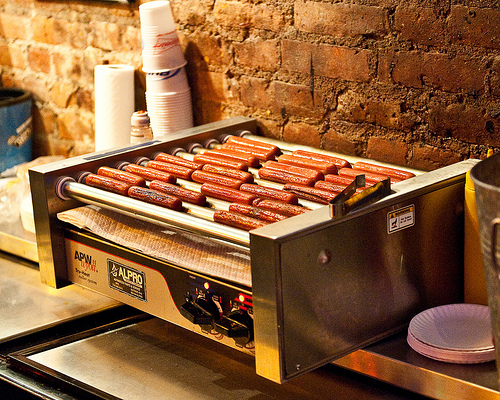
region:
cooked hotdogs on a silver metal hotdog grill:
[28, 115, 480, 383]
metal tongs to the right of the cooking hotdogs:
[85, 135, 414, 230]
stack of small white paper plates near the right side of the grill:
[251, 157, 498, 384]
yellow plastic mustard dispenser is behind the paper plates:
[408, 149, 498, 363]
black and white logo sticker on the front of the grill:
[27, 169, 282, 384]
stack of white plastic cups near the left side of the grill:
[28, 1, 255, 288]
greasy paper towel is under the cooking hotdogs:
[56, 136, 417, 288]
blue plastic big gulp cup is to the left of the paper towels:
[1, 1, 133, 174]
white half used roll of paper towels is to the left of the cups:
[93, 0, 191, 152]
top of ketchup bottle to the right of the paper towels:
[94, 65, 152, 149]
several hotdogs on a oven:
[22, 106, 458, 328]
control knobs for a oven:
[176, 287, 255, 344]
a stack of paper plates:
[406, 264, 496, 379]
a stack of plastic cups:
[128, 10, 198, 152]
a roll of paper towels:
[82, 50, 131, 164]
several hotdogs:
[186, 150, 356, 232]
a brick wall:
[283, 34, 428, 125]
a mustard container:
[444, 138, 496, 309]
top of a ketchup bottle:
[105, 100, 160, 156]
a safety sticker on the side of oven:
[376, 195, 439, 242]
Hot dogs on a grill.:
[78, 135, 417, 228]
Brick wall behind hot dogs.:
[3, 4, 497, 187]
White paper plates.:
[406, 299, 497, 366]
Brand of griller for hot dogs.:
[64, 242, 156, 304]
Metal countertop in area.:
[0, 155, 497, 398]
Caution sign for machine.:
[382, 202, 422, 236]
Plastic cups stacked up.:
[136, 1, 210, 139]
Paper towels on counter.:
[91, 61, 141, 153]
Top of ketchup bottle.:
[126, 108, 156, 148]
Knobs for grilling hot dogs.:
[177, 285, 266, 354]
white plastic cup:
[138, 0, 186, 73]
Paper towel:
[93, 62, 134, 138]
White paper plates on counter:
[406, 305, 498, 370]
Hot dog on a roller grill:
[84, 170, 129, 195]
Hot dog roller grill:
[29, 110, 436, 378]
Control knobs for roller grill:
[187, 292, 250, 352]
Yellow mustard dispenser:
[464, 147, 498, 302]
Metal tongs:
[332, 171, 392, 214]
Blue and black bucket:
[1, 85, 29, 174]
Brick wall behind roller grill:
[226, 5, 498, 117]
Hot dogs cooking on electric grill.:
[150, 147, 335, 233]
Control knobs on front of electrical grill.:
[167, 276, 277, 364]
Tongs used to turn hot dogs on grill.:
[321, 162, 396, 227]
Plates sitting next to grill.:
[404, 294, 498, 366]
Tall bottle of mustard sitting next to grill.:
[460, 134, 495, 306]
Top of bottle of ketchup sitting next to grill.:
[120, 108, 162, 145]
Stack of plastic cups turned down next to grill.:
[127, 3, 209, 135]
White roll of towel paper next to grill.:
[88, 56, 132, 158]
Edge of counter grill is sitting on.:
[369, 348, 499, 397]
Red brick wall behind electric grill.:
[278, 11, 498, 148]